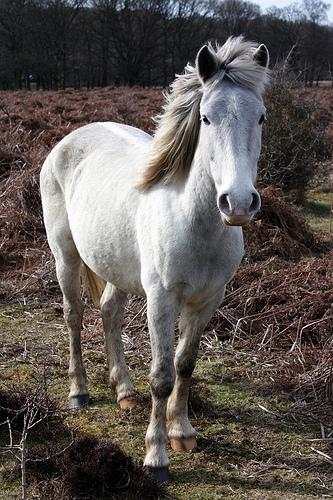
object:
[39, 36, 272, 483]
horse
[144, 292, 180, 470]
leg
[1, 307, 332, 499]
grass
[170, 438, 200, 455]
hoof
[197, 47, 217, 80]
ear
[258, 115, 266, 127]
eye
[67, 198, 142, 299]
belly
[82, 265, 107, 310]
tail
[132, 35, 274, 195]
mane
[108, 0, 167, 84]
tree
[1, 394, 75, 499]
stick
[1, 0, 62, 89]
background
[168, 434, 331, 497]
shadow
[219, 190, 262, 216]
nose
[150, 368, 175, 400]
knee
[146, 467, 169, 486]
black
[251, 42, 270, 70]
ear